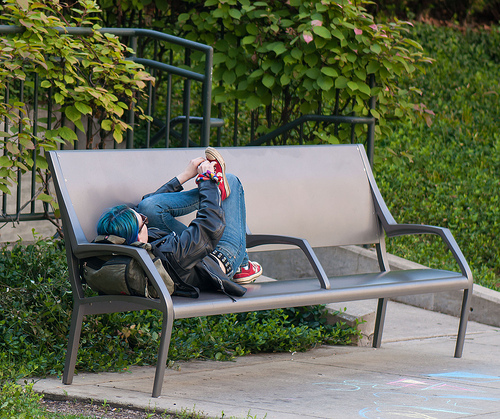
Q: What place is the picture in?
A: It is at the sidewalk.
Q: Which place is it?
A: It is a sidewalk.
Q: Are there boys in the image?
A: No, there are no boys.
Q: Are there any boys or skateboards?
A: No, there are no boys or skateboards.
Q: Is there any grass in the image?
A: Yes, there is grass.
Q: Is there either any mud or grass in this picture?
A: Yes, there is grass.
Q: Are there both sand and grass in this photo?
A: No, there is grass but no sand.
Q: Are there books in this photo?
A: No, there are no books.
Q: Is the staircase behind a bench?
A: Yes, the staircase is behind a bench.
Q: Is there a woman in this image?
A: Yes, there is a woman.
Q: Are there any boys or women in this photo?
A: Yes, there is a woman.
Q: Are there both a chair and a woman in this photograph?
A: No, there is a woman but no chairs.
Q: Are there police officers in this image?
A: No, there are no police officers.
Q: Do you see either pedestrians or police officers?
A: No, there are no police officers or pedestrians.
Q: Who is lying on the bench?
A: The woman is lying on the bench.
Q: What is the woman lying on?
A: The woman is lying on the bench.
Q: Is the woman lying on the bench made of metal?
A: Yes, the woman is lying on the bench.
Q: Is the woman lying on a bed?
A: No, the woman is lying on the bench.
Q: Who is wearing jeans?
A: The woman is wearing jeans.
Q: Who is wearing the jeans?
A: The woman is wearing jeans.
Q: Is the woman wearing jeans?
A: Yes, the woman is wearing jeans.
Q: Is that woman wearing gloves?
A: No, the woman is wearing jeans.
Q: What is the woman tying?
A: The woman is tying the shoe.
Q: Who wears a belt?
A: The woman wears a belt.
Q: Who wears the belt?
A: The woman wears a belt.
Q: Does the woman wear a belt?
A: Yes, the woman wears a belt.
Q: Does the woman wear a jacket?
A: No, the woman wears a belt.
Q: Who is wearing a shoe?
A: The woman is wearing a shoe.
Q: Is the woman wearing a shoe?
A: Yes, the woman is wearing a shoe.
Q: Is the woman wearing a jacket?
A: No, the woman is wearing a shoe.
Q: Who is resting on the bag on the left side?
A: The woman is resting on the backpack.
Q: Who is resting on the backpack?
A: The woman is resting on the backpack.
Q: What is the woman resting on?
A: The woman is resting on the backpack.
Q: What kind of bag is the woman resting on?
A: The woman is resting on the backpack.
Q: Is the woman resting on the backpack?
A: Yes, the woman is resting on the backpack.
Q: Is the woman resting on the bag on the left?
A: Yes, the woman is resting on the backpack.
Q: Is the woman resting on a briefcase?
A: No, the woman is resting on the backpack.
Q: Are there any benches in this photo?
A: Yes, there is a bench.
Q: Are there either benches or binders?
A: Yes, there is a bench.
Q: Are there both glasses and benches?
A: Yes, there are both a bench and glasses.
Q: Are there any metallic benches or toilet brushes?
A: Yes, there is a metal bench.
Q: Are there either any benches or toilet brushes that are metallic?
A: Yes, the bench is metallic.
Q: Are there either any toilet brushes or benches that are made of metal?
A: Yes, the bench is made of metal.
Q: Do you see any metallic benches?
A: Yes, there is a metal bench.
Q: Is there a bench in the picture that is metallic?
A: Yes, there is a bench that is metallic.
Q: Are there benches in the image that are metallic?
A: Yes, there is a bench that is metallic.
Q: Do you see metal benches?
A: Yes, there is a bench that is made of metal.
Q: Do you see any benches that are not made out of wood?
A: Yes, there is a bench that is made of metal.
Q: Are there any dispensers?
A: No, there are no dispensers.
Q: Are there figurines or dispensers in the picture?
A: No, there are no dispensers or figurines.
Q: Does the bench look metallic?
A: Yes, the bench is metallic.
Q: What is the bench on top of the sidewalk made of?
A: The bench is made of metal.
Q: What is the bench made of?
A: The bench is made of metal.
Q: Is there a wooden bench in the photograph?
A: No, there is a bench but it is metallic.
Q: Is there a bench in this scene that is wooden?
A: No, there is a bench but it is metallic.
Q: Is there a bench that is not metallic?
A: No, there is a bench but it is metallic.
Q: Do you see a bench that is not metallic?
A: No, there is a bench but it is metallic.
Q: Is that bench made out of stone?
A: No, the bench is made of metal.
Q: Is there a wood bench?
A: No, there is a bench but it is made of metal.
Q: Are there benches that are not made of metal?
A: No, there is a bench but it is made of metal.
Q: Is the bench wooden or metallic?
A: The bench is metallic.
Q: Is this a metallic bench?
A: Yes, this is a metallic bench.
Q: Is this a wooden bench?
A: No, this is a metallic bench.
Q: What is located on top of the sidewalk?
A: The bench is on top of the sidewalk.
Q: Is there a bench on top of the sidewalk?
A: Yes, there is a bench on top of the sidewalk.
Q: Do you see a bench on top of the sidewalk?
A: Yes, there is a bench on top of the sidewalk.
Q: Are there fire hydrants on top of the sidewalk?
A: No, there is a bench on top of the sidewalk.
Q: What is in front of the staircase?
A: The bench is in front of the staircase.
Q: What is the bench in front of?
A: The bench is in front of the staircase.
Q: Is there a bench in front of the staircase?
A: Yes, there is a bench in front of the staircase.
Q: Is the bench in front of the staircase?
A: Yes, the bench is in front of the staircase.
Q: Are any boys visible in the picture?
A: No, there are no boys.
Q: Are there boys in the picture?
A: No, there are no boys.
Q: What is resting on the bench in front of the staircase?
A: The shoe is resting on the bench.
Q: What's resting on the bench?
A: The shoe is resting on the bench.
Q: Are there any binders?
A: No, there are no binders.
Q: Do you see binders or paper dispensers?
A: No, there are no binders or paper dispensers.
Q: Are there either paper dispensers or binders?
A: No, there are no binders or paper dispensers.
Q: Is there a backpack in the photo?
A: Yes, there is a backpack.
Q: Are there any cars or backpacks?
A: Yes, there is a backpack.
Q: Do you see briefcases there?
A: No, there are no briefcases.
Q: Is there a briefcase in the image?
A: No, there are no briefcases.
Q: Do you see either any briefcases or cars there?
A: No, there are no briefcases or cars.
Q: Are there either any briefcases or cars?
A: No, there are no briefcases or cars.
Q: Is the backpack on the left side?
A: Yes, the backpack is on the left of the image.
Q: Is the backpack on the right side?
A: No, the backpack is on the left of the image.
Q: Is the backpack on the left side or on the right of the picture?
A: The backpack is on the left of the image.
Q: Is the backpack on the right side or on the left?
A: The backpack is on the left of the image.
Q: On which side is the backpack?
A: The backpack is on the left of the image.